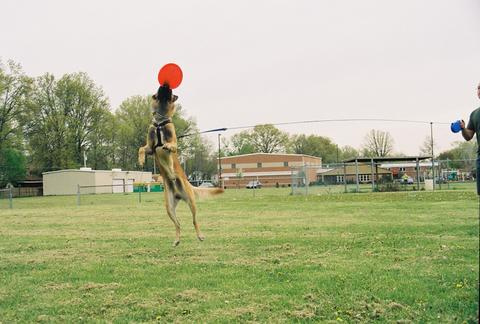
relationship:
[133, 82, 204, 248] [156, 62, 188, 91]
dog catches frisbee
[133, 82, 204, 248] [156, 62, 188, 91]
dog catching frisbee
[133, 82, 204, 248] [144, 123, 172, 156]
dog wears harness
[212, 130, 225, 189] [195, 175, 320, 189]
pole in parking lot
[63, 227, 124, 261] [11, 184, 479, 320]
grass covers area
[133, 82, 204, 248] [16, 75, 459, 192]
dog in air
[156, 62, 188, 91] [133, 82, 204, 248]
frisbee caught by dog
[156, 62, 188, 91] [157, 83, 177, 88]
frisbee in mouth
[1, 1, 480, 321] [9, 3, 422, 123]
photo taken during day